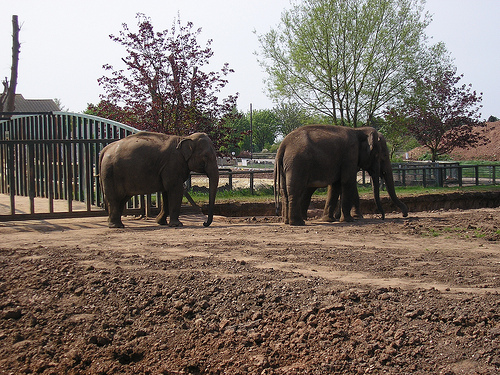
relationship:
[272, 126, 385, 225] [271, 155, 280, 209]
elephant has tail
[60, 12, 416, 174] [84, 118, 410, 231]
sky above elephants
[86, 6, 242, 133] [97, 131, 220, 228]
tree near elephant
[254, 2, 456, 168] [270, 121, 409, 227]
tree near elephant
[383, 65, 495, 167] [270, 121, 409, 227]
tree near elephant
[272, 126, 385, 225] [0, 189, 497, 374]
elephant standing in enclosure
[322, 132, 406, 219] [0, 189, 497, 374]
elephant standing in enclosure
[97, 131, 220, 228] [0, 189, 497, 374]
elephant standing in enclosure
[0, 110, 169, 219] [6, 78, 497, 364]
fence near elephant enclosure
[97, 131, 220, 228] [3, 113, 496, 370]
elephant standing in enclosure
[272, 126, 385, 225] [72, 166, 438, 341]
elephant standing in enclosure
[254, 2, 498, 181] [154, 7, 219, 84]
tree with leaves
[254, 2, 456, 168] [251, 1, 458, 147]
tree with leaves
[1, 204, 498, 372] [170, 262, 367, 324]
dirt covering ground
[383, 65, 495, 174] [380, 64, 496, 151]
tree with leaves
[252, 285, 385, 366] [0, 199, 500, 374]
ground covered soil